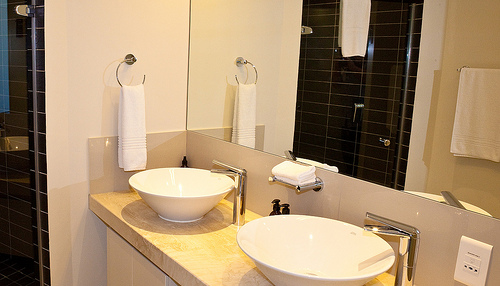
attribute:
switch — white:
[448, 233, 497, 284]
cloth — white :
[118, 86, 154, 174]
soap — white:
[270, 155, 342, 207]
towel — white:
[115, 83, 149, 172]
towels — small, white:
[271, 156, 318, 182]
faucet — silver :
[211, 156, 246, 217]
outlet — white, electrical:
[456, 241, 483, 281]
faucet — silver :
[366, 211, 419, 284]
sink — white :
[236, 210, 397, 284]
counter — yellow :
[182, 222, 234, 284]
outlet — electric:
[453, 235, 496, 283]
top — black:
[267, 199, 277, 204]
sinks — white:
[130, 164, 397, 284]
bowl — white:
[111, 133, 258, 251]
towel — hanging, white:
[445, 61, 492, 99]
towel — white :
[451, 66, 498, 160]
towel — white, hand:
[118, 82, 150, 172]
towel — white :
[111, 50, 189, 171]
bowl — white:
[129, 166, 233, 226]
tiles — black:
[0, 1, 53, 281]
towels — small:
[113, 75, 154, 173]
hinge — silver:
[347, 98, 367, 109]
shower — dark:
[0, 2, 52, 283]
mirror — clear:
[188, 0, 497, 214]